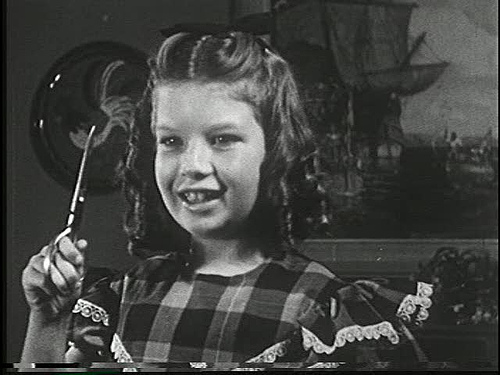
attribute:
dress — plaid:
[77, 236, 397, 368]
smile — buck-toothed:
[176, 185, 227, 211]